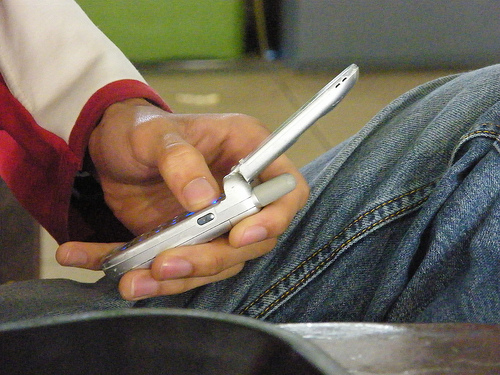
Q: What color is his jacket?
A: Red and white.